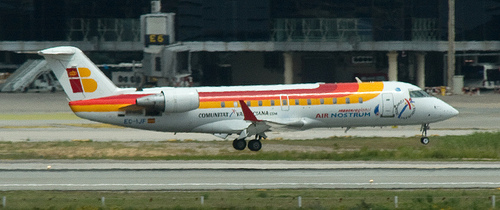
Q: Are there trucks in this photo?
A: No, there are no trucks.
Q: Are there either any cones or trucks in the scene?
A: No, there are no trucks or cones.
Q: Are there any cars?
A: No, there are no cars.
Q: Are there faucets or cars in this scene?
A: No, there are no cars or faucets.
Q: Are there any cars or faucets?
A: No, there are no cars or faucets.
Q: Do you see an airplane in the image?
A: Yes, there is an airplane.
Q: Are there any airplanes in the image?
A: Yes, there is an airplane.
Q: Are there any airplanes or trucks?
A: Yes, there is an airplane.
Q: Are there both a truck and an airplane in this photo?
A: No, there is an airplane but no trucks.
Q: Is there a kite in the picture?
A: No, there are no kites.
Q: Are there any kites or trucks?
A: No, there are no kites or trucks.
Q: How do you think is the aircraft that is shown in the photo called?
A: The aircraft is an airplane.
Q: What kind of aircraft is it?
A: The aircraft is an airplane.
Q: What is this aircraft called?
A: This is an airplane.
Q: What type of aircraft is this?
A: This is an airplane.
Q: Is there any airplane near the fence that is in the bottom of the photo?
A: Yes, there is an airplane near the fence.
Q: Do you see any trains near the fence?
A: No, there is an airplane near the fence.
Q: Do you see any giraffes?
A: No, there are no giraffes.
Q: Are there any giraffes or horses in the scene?
A: No, there are no giraffes or horses.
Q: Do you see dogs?
A: No, there are no dogs.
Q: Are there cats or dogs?
A: No, there are no dogs or cats.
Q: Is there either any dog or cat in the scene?
A: No, there are no dogs or cats.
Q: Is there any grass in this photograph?
A: Yes, there is grass.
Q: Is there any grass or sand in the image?
A: Yes, there is grass.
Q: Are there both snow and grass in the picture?
A: No, there is grass but no snow.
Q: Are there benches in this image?
A: No, there are no benches.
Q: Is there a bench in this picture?
A: No, there are no benches.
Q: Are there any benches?
A: No, there are no benches.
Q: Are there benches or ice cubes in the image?
A: No, there are no benches or ice cubes.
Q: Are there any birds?
A: No, there are no birds.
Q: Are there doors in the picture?
A: Yes, there is a door.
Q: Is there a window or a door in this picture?
A: Yes, there is a door.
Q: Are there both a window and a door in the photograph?
A: Yes, there are both a door and a window.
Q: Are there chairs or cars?
A: No, there are no cars or chairs.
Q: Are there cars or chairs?
A: No, there are no cars or chairs.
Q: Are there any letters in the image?
A: Yes, there are letters.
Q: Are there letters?
A: Yes, there are letters.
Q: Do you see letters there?
A: Yes, there are letters.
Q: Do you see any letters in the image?
A: Yes, there are letters.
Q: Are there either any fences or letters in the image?
A: Yes, there are letters.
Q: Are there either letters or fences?
A: Yes, there are letters.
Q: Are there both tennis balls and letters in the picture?
A: No, there are letters but no tennis balls.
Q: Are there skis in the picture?
A: No, there are no skis.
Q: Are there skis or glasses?
A: No, there are no skis or glasses.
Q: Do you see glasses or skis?
A: No, there are no skis or glasses.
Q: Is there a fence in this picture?
A: Yes, there is a fence.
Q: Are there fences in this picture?
A: Yes, there is a fence.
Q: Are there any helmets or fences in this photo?
A: Yes, there is a fence.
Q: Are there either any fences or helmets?
A: Yes, there is a fence.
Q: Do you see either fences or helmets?
A: Yes, there is a fence.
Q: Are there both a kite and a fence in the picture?
A: No, there is a fence but no kites.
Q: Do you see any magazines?
A: No, there are no magazines.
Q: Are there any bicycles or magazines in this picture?
A: No, there are no magazines or bicycles.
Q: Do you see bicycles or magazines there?
A: No, there are no magazines or bicycles.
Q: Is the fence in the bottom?
A: Yes, the fence is in the bottom of the image.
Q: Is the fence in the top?
A: No, the fence is in the bottom of the image.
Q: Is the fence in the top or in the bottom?
A: The fence is in the bottom of the image.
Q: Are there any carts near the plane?
A: No, there is a fence near the plane.